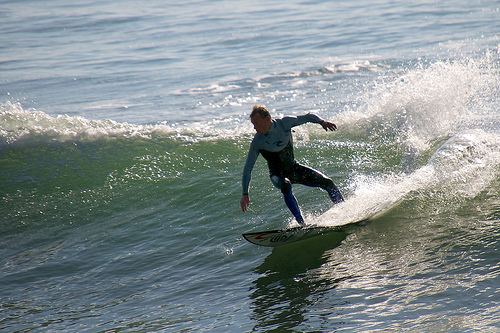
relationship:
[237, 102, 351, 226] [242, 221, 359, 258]
man on top of surfboard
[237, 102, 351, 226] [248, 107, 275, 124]
man has hair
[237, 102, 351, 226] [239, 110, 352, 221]
man has wetsuit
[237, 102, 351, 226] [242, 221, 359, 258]
man riding surfboard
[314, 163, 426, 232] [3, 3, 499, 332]
wake in water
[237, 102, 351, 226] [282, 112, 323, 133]
man has arm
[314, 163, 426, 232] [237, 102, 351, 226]
wake behind man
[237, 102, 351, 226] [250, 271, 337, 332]
man makes reflection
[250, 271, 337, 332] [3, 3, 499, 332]
reflection in water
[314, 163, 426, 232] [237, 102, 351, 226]
wake splashing behind man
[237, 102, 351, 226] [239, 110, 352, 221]
man wearing wetsuit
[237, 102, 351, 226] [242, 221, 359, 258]
man riding on surfboard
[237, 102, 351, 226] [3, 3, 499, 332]
man surrounded by water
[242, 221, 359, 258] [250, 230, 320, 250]
surfboard has bottom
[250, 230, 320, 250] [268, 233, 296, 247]
bottom has graphic design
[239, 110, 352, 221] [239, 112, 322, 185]
wetsuit has top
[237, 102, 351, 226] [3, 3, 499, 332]
man surfing in water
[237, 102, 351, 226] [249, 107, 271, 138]
man has head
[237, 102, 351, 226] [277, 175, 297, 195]
man has knee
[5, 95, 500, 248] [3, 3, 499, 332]
wave in water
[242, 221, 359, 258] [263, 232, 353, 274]
surfboard has reflection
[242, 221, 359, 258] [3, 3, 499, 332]
surfboard in water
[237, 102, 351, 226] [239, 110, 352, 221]
man in wetsuit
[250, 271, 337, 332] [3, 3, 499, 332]
reflection across water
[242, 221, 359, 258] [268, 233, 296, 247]
surfboard has graphic design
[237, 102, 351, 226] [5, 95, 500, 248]
man surfing on wave